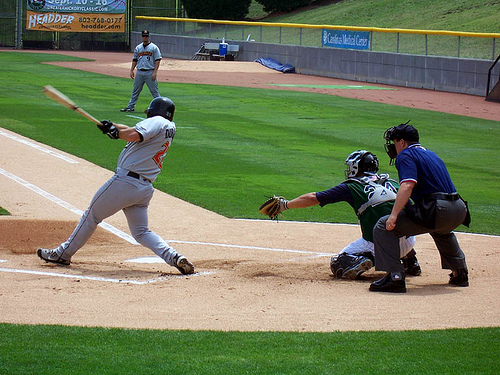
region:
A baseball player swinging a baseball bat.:
[36, 82, 193, 274]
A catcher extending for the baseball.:
[260, 148, 417, 275]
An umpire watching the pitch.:
[369, 125, 468, 288]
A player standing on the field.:
[121, 31, 163, 113]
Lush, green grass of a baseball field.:
[191, 90, 308, 183]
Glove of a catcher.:
[258, 193, 287, 223]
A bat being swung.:
[40, 84, 102, 125]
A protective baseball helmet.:
[143, 93, 175, 117]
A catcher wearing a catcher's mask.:
[345, 141, 383, 173]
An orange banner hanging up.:
[23, 12, 123, 34]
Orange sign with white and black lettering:
[24, 12, 127, 37]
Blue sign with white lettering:
[318, 26, 371, 50]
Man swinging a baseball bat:
[27, 85, 179, 272]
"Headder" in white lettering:
[21, 12, 74, 33]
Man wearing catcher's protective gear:
[337, 145, 384, 218]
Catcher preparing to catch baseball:
[255, 146, 382, 279]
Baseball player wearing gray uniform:
[113, 90, 179, 180]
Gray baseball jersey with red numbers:
[111, 114, 178, 182]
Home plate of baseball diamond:
[125, 255, 168, 267]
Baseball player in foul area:
[125, 25, 164, 95]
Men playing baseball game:
[35, 30, 471, 293]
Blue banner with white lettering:
[319, 28, 372, 48]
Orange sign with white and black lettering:
[25, 9, 125, 32]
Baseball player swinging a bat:
[39, 89, 176, 271]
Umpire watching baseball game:
[377, 120, 429, 287]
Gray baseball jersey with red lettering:
[115, 114, 178, 179]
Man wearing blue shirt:
[378, 120, 450, 198]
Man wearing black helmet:
[138, 91, 179, 126]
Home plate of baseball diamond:
[120, 252, 162, 269]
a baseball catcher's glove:
[259, 193, 286, 220]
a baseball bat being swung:
[40, 83, 105, 125]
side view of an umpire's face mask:
[383, 129, 398, 167]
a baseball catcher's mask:
[339, 149, 378, 175]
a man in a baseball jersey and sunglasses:
[129, 30, 162, 96]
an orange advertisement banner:
[24, 12, 124, 32]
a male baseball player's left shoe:
[35, 248, 71, 265]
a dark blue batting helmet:
[143, 96, 175, 121]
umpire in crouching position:
[375, 126, 462, 277]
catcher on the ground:
[307, 139, 387, 313]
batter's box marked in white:
[38, 239, 317, 282]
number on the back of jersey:
[151, 127, 171, 169]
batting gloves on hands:
[88, 109, 125, 137]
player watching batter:
[100, 4, 163, 99]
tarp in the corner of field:
[246, 58, 290, 78]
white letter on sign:
[27, 10, 39, 30]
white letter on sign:
[33, 12, 43, 29]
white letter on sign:
[46, 10, 56, 27]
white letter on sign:
[54, 9, 61, 29]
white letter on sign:
[58, 9, 69, 24]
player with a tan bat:
[30, 73, 201, 282]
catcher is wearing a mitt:
[254, 139, 388, 234]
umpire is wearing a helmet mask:
[378, 121, 443, 214]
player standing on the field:
[113, 20, 173, 97]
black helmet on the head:
[138, 91, 177, 121]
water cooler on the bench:
[213, 37, 231, 57]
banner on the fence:
[322, 27, 369, 50]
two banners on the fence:
[22, 3, 132, 41]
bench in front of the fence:
[193, 43, 213, 59]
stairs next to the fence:
[482, 62, 498, 106]